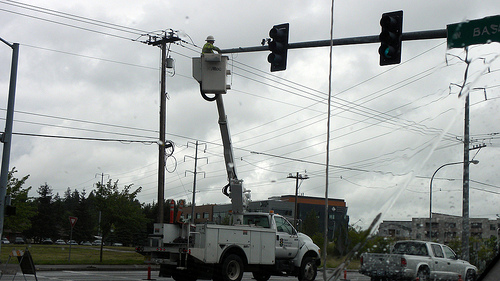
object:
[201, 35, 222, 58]
man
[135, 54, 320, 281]
truck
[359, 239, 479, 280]
pickup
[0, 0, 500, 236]
sky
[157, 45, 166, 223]
street pole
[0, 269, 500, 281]
street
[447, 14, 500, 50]
street sign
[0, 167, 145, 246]
trees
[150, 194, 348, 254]
buildings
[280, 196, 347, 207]
orange roof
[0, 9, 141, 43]
wires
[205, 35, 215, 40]
hat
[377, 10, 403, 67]
traffic light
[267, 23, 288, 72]
traffic light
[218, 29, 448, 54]
pole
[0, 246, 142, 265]
grass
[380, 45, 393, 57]
light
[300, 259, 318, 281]
tires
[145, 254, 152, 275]
cones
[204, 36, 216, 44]
head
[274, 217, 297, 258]
door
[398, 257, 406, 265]
tail light